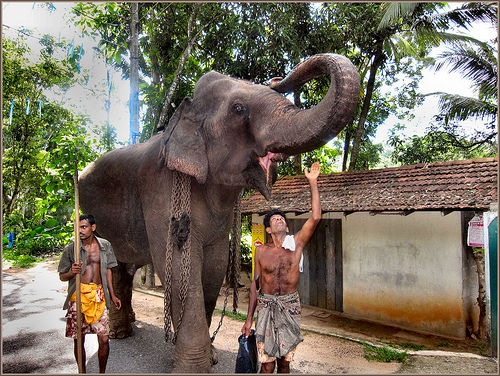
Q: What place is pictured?
A: It is a path.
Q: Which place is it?
A: It is a path.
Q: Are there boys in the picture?
A: No, there are no boys.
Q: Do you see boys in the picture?
A: No, there are no boys.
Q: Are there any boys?
A: No, there are no boys.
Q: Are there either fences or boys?
A: No, there are no boys or fences.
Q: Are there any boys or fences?
A: No, there are no boys or fences.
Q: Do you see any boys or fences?
A: No, there are no boys or fences.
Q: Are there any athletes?
A: No, there are no athletes.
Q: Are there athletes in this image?
A: No, there are no athletes.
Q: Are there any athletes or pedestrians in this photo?
A: No, there are no athletes or pedestrians.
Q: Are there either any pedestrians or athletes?
A: No, there are no athletes or pedestrians.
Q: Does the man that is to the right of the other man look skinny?
A: Yes, the man is skinny.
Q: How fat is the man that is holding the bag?
A: The man is skinny.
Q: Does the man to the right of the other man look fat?
A: No, the man is skinny.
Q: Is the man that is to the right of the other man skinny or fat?
A: The man is skinny.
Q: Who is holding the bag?
A: The man is holding the bag.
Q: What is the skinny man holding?
A: The man is holding the bag.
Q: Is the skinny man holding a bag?
A: Yes, the man is holding a bag.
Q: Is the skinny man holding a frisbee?
A: No, the man is holding a bag.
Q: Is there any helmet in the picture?
A: No, there are no helmets.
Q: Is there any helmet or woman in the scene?
A: No, there are no helmets or women.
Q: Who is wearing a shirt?
A: The man is wearing a shirt.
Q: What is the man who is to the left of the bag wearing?
A: The man is wearing a shirt.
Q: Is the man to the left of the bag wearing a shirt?
A: Yes, the man is wearing a shirt.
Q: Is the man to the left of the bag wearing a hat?
A: No, the man is wearing a shirt.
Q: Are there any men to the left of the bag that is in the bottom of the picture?
A: Yes, there is a man to the left of the bag.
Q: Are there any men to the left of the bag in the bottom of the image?
A: Yes, there is a man to the left of the bag.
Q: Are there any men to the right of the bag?
A: No, the man is to the left of the bag.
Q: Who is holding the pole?
A: The man is holding the pole.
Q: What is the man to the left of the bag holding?
A: The man is holding the pole.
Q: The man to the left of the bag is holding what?
A: The man is holding the pole.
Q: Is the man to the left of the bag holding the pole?
A: Yes, the man is holding the pole.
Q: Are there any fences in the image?
A: No, there are no fences.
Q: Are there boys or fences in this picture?
A: No, there are no fences or boys.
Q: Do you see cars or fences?
A: No, there are no fences or cars.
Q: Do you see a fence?
A: No, there are no fences.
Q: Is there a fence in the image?
A: No, there are no fences.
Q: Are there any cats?
A: No, there are no cats.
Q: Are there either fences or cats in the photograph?
A: No, there are no cats or fences.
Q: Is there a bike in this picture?
A: No, there are no bikes.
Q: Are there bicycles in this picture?
A: No, there are no bicycles.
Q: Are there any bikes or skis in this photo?
A: No, there are no bikes or skis.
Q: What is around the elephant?
A: The chain is around the elephant.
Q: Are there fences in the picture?
A: No, there are no fences.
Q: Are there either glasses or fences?
A: No, there are no fences or glasses.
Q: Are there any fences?
A: No, there are no fences.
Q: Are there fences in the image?
A: No, there are no fences.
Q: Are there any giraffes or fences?
A: No, there are no fences or giraffes.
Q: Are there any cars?
A: No, there are no cars.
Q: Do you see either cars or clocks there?
A: No, there are no cars or clocks.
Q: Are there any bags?
A: Yes, there is a bag.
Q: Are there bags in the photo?
A: Yes, there is a bag.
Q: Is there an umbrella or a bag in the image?
A: Yes, there is a bag.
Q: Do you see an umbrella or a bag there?
A: Yes, there is a bag.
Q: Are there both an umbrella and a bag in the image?
A: No, there is a bag but no umbrellas.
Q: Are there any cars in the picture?
A: No, there are no cars.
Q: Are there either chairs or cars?
A: No, there are no cars or chairs.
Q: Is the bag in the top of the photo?
A: No, the bag is in the bottom of the image.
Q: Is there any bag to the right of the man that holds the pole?
A: Yes, there is a bag to the right of the man.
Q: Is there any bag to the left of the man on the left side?
A: No, the bag is to the right of the man.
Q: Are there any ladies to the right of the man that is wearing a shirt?
A: No, there is a bag to the right of the man.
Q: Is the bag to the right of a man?
A: Yes, the bag is to the right of a man.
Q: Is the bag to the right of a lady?
A: No, the bag is to the right of a man.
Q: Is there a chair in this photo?
A: No, there are no chairs.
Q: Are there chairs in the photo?
A: No, there are no chairs.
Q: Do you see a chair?
A: No, there are no chairs.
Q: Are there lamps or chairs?
A: No, there are no chairs or lamps.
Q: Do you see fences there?
A: No, there are no fences.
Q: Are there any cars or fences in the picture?
A: No, there are no fences or cars.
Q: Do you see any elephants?
A: Yes, there is an elephant.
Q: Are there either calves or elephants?
A: Yes, there is an elephant.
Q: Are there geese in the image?
A: No, there are no geese.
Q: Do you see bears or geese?
A: No, there are no geese or bears.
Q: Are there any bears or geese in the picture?
A: No, there are no geese or bears.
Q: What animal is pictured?
A: The animal is an elephant.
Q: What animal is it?
A: The animal is an elephant.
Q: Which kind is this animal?
A: That is an elephant.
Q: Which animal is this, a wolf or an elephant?
A: That is an elephant.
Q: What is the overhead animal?
A: The animal is an elephant.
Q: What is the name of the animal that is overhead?
A: The animal is an elephant.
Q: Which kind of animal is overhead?
A: The animal is an elephant.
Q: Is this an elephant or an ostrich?
A: This is an elephant.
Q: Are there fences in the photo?
A: No, there are no fences.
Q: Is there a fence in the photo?
A: No, there are no fences.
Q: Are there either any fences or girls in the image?
A: No, there are no fences or girls.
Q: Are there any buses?
A: No, there are no buses.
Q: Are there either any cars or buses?
A: No, there are no buses or cars.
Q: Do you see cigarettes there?
A: No, there are no cigarettes.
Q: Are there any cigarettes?
A: No, there are no cigarettes.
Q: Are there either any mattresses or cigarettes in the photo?
A: No, there are no cigarettes or mattresses.